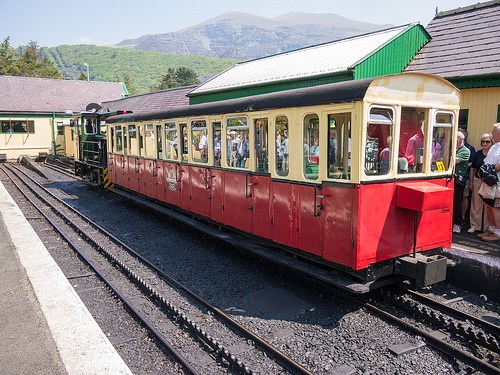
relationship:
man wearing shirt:
[451, 127, 471, 235] [455, 143, 472, 187]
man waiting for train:
[451, 127, 471, 235] [62, 67, 457, 298]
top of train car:
[108, 72, 460, 182] [103, 69, 460, 295]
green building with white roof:
[353, 25, 430, 79] [190, 28, 387, 91]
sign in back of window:
[430, 159, 447, 174] [427, 106, 465, 180]